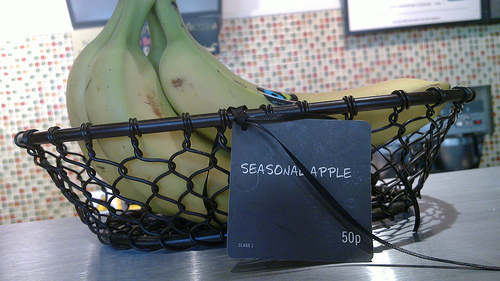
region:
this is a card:
[241, 123, 363, 239]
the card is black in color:
[268, 210, 284, 225]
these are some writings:
[238, 158, 354, 180]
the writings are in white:
[240, 158, 350, 175]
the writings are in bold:
[236, 150, 352, 180]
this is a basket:
[133, 121, 205, 231]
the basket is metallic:
[116, 129, 188, 228]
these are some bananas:
[86, 40, 251, 113]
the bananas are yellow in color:
[362, 83, 388, 94]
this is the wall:
[280, 15, 342, 79]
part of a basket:
[422, 122, 437, 132]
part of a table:
[434, 228, 445, 242]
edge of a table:
[476, 170, 487, 175]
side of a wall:
[305, 36, 312, 49]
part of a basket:
[377, 79, 382, 98]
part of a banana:
[193, 67, 205, 85]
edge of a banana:
[168, 45, 194, 82]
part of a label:
[235, 173, 250, 190]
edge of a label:
[291, 240, 307, 272]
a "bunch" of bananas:
[60, 5, 436, 207]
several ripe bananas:
[52, 5, 449, 225]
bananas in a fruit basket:
[7, 11, 483, 255]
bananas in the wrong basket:
[10, 7, 484, 254]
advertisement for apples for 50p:
[227, 115, 379, 272]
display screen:
[327, 0, 492, 42]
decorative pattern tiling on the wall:
[231, 15, 343, 82]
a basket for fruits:
[10, 75, 486, 255]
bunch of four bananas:
[60, 0, 455, 230]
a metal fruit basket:
[6, 70, 479, 258]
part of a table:
[443, 199, 452, 216]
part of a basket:
[405, 144, 410, 152]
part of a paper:
[340, 201, 348, 216]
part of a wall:
[346, 53, 358, 69]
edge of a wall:
[298, 43, 299, 49]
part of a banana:
[152, 68, 169, 96]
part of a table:
[41, 210, 63, 240]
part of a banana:
[149, 28, 152, 33]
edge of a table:
[422, 190, 434, 209]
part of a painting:
[361, 20, 371, 35]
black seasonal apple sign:
[233, 122, 372, 264]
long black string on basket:
[376, 232, 498, 271]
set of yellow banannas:
[62, 4, 447, 117]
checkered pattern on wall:
[290, 13, 337, 74]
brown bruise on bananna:
[170, 75, 194, 95]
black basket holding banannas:
[19, 90, 469, 247]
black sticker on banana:
[260, 90, 300, 100]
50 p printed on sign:
[336, 227, 361, 247]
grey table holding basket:
[0, 219, 80, 279]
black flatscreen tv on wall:
[337, 0, 484, 35]